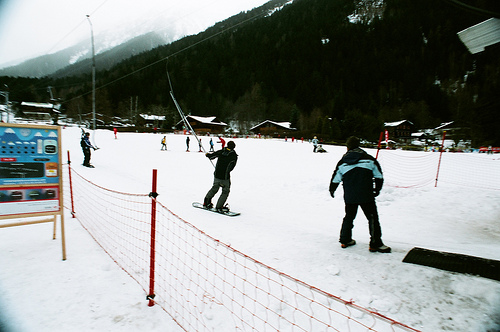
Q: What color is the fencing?
A: Red.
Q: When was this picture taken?
A: Daytime.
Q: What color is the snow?
A: White.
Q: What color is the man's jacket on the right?
A: Black and blue.